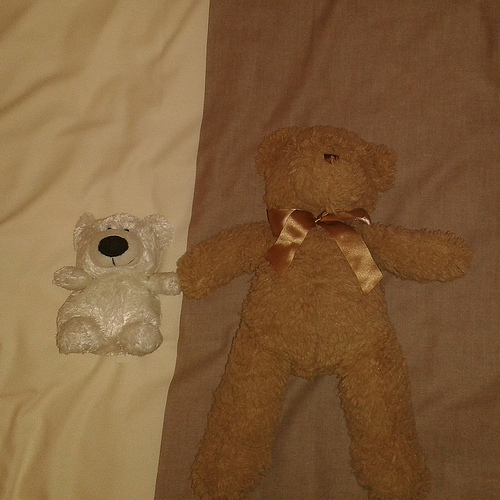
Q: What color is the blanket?
A: Tan, brown.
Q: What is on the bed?
A: Stuffed bears.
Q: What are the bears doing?
A: Holding hands.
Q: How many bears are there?
A: 2.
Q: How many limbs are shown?
A: 8.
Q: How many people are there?
A: 0.